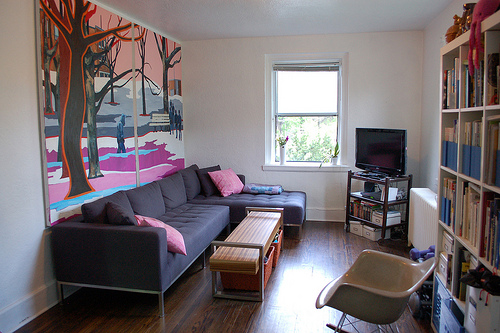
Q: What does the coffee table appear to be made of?
A: Wood and metal.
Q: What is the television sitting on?
A: A stand with shelves.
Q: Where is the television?
A: In the corner of the room.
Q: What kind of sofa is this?
A: Sectional.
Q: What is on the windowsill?
A: Vases.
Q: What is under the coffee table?
A: Two boxes.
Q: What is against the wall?
A: A black couch.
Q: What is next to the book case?
A: A white chair.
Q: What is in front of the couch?
A: A coffee table.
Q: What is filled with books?
A: A bookcase.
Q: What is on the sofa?
A: A few pillows.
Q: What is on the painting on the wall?
A: A winter scenery.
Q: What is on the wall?
A: Picture.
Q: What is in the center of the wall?
A: Window.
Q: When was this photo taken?
A: Daytime.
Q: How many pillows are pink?
A: 2.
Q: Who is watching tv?
A: No one.